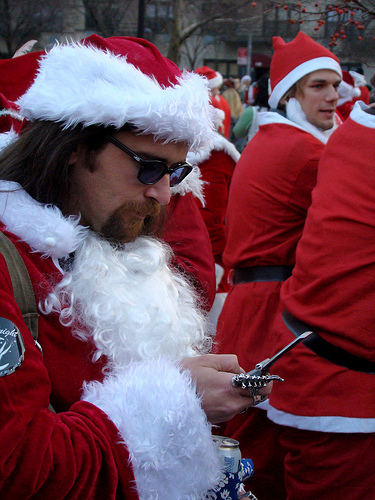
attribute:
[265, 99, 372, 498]
person — wearing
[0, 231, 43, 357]
strap — brown, sholder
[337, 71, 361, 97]
santa hat — red, white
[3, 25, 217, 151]
hat — white, red, Santa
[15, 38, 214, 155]
fur — white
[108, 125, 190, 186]
sunglasses — black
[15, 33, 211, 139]
santa hat — red, white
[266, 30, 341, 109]
santa hat — white, red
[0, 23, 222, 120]
hat — red, white, Santa Claus, dress up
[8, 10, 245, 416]
santa — black, weird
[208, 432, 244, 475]
can — metal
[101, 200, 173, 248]
goatee — brown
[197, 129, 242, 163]
cuff — fluffy, white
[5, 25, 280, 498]
santa — texting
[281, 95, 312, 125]
ground — black, brick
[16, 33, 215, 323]
man — holding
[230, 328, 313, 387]
phone — flip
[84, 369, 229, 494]
cuff — fur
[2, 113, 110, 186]
hair — brown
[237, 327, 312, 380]
phone — gray, black, flip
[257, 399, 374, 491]
pants — red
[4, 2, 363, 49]
building — brown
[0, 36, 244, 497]
santa — fake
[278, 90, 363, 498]
santa — fake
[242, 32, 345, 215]
santa — fake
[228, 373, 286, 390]
ring — long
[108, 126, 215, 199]
sunglasses — black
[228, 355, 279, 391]
bulbs — red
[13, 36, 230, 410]
person — wearing